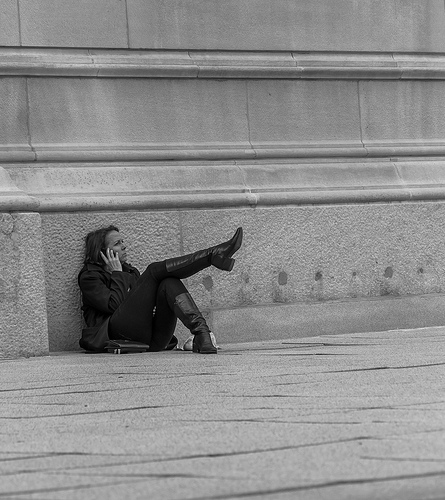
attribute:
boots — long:
[164, 228, 249, 271]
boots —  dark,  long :
[168, 294, 216, 353]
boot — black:
[173, 291, 218, 357]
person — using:
[74, 218, 250, 356]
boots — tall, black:
[166, 227, 243, 277]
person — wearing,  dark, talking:
[77, 225, 243, 353]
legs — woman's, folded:
[116, 222, 245, 351]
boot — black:
[164, 227, 243, 277]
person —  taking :
[53, 192, 239, 376]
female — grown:
[88, 223, 233, 353]